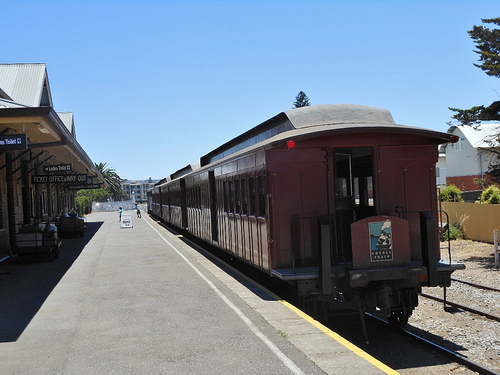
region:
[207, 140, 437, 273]
the train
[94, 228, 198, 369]
the sidewalk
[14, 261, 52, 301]
a shadow on the ground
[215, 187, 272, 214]
windows on the train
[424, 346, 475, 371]
train tracks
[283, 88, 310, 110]
the top of a tree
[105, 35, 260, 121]
the sky is blue and clear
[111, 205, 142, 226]
a sign on the sidewalk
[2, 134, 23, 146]
sign on the building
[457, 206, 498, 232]
a wall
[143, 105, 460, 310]
the train is at the station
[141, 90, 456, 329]
the train is not moving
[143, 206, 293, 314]
a shadow is on the platform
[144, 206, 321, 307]
the train is casting a shadow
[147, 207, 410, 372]
the platform edge has a yellow line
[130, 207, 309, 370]
a white line runs across the platform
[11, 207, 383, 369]
the platform is made of concrete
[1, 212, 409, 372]
the concrete is grey in color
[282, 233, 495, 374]
the ground has gravel spread out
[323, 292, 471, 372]
a shadow is on the ground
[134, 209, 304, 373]
white painted line on platform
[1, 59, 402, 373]
train platform with building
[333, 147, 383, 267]
door on rear of train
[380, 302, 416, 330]
wheel of a train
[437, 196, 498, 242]
brown fence around perimeter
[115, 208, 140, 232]
sign in middle of platform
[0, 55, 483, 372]
train station with train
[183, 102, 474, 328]
red train with observation deck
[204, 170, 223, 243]
door on side of train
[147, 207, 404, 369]
yellow line on train platform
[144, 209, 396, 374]
Yellow caution line painted on edge of train platform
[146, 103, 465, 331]
Red train cars on train tracks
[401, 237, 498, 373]
Stony area beside rail road tracks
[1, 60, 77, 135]
Two pointed metal roofs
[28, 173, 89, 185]
Black and white sign advertising ticket office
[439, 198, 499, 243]
Brown fence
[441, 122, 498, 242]
White building with red strip behind fence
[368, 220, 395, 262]
Logo in blue, black and white on train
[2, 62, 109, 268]
Light colored building on the left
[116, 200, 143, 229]
Two people on the train platform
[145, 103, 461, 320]
Train parked at station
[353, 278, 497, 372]
Tracks for trains to ride on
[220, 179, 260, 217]
Windows for passengers to look through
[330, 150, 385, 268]
Door to enter the train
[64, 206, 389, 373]
Train platform outside station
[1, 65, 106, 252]
Train station building next to platform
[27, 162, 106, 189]
Signs hanging outside of building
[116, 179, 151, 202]
White building in the background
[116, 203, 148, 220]
People walking on the train platform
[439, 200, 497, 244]
Wall separating neighborhood from train tracks